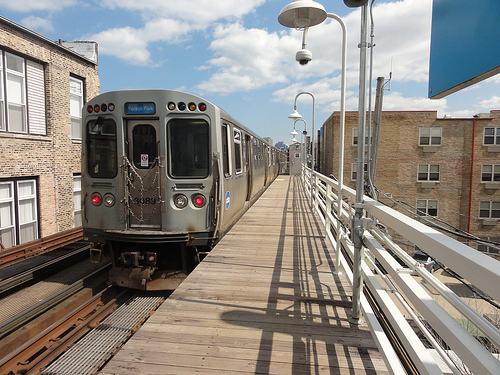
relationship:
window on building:
[418, 164, 438, 182] [334, 108, 480, 238]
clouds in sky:
[215, 51, 274, 79] [251, 100, 304, 133]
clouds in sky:
[0, 0, 499, 118] [242, 100, 275, 124]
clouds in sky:
[0, 0, 499, 118] [245, 113, 305, 133]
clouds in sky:
[0, 0, 499, 118] [244, 100, 283, 130]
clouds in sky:
[0, 0, 499, 118] [254, 100, 294, 123]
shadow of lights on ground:
[228, 293, 374, 343] [162, 244, 389, 375]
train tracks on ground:
[16, 283, 108, 367] [1, 317, 180, 375]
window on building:
[16, 187, 42, 240] [12, 172, 43, 192]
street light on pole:
[281, 82, 318, 143] [307, 118, 316, 236]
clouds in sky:
[0, 0, 499, 118] [261, 102, 271, 115]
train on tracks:
[89, 79, 215, 254] [20, 300, 220, 375]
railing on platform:
[324, 134, 498, 375] [174, 284, 340, 375]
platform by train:
[239, 170, 349, 375] [101, 124, 214, 284]